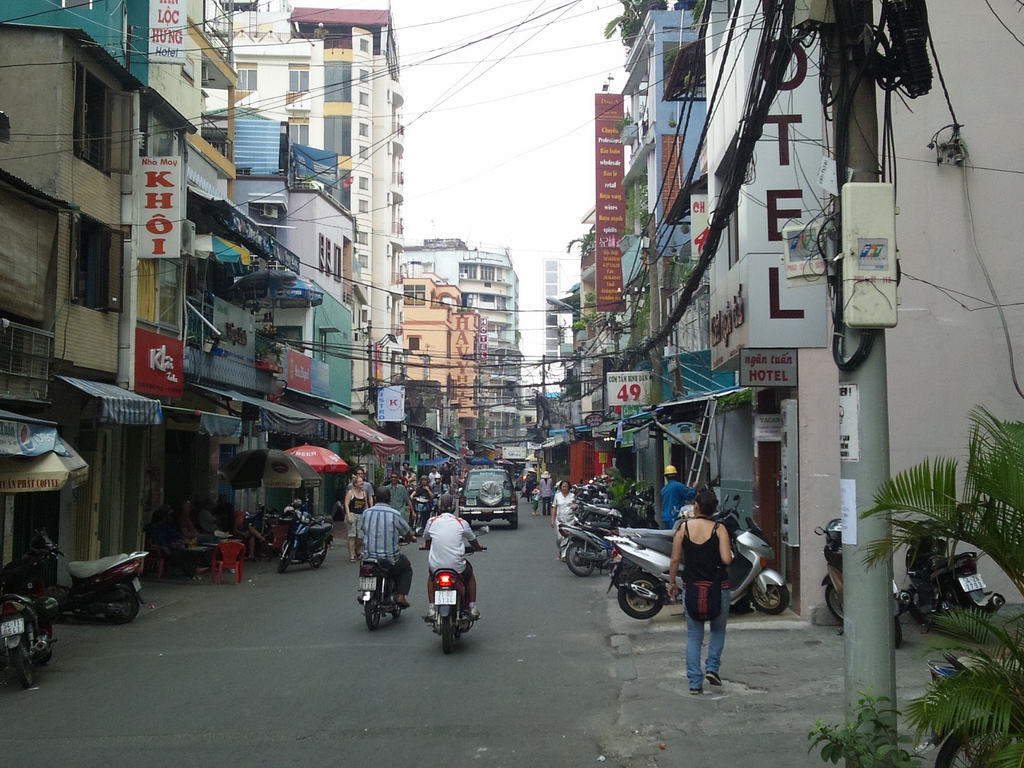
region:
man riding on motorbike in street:
[361, 475, 403, 622]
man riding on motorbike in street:
[413, 482, 475, 651]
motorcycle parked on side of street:
[614, 512, 788, 636]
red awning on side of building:
[336, 398, 390, 466]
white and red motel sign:
[742, 13, 828, 342]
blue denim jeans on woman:
[685, 597, 737, 686]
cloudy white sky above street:
[399, 4, 597, 254]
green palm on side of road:
[840, 398, 995, 766]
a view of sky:
[460, 70, 556, 179]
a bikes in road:
[293, 470, 585, 683]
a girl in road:
[653, 476, 789, 739]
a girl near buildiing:
[631, 492, 784, 767]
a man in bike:
[351, 497, 427, 568]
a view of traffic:
[236, 304, 630, 684]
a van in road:
[451, 439, 540, 556]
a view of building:
[328, 208, 535, 449]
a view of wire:
[385, 42, 475, 104]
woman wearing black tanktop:
[662, 483, 738, 695]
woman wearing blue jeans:
[665, 484, 738, 696]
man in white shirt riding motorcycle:
[415, 495, 489, 661]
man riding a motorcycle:
[355, 481, 417, 631]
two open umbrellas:
[225, 439, 347, 490]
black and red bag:
[680, 541, 726, 627]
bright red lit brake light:
[435, 569, 454, 589]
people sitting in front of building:
[140, 487, 277, 580]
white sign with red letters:
[134, 152, 183, 263]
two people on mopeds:
[339, 486, 551, 711]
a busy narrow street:
[71, 97, 855, 645]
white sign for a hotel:
[617, 9, 878, 368]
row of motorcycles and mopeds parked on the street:
[490, 417, 820, 642]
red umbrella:
[256, 423, 386, 500]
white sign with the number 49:
[589, 356, 660, 417]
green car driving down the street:
[450, 435, 542, 543]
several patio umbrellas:
[171, 211, 331, 348]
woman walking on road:
[658, 488, 751, 710]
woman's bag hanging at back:
[679, 577, 719, 626]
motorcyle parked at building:
[597, 518, 797, 637]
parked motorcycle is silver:
[602, 515, 790, 637]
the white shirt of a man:
[418, 522, 488, 592]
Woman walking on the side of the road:
[672, 486, 742, 693]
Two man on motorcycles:
[354, 483, 488, 652]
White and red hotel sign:
[735, 339, 803, 394]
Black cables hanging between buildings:
[5, 3, 742, 434]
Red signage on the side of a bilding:
[594, 85, 632, 320]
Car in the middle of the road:
[457, 458, 522, 534]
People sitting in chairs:
[141, 471, 298, 586]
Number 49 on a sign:
[599, 363, 657, 409]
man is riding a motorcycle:
[417, 493, 487, 658]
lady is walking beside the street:
[663, 487, 739, 690]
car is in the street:
[460, 465, 524, 527]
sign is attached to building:
[135, 155, 183, 257]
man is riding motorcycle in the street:
[357, 486, 421, 635]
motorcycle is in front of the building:
[601, 489, 789, 625]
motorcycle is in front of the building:
[0, 514, 154, 628]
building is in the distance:
[398, 275, 487, 435]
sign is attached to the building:
[591, 88, 636, 316]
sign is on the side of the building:
[738, 6, 840, 352]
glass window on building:
[76, 214, 116, 314]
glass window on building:
[73, 69, 112, 172]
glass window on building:
[161, 262, 177, 332]